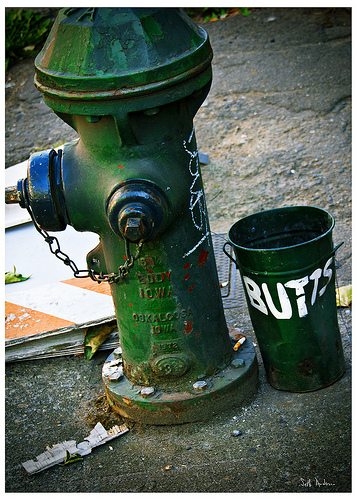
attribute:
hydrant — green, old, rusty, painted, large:
[4, 8, 259, 426]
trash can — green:
[222, 206, 347, 392]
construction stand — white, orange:
[6, 160, 140, 359]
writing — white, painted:
[241, 258, 333, 320]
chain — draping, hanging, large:
[25, 200, 142, 282]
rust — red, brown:
[182, 247, 210, 340]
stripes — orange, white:
[4, 275, 114, 344]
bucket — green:
[224, 204, 346, 392]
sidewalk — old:
[6, 8, 353, 492]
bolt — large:
[119, 207, 153, 241]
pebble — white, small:
[233, 430, 241, 435]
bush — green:
[7, 9, 234, 79]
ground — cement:
[8, 8, 348, 490]